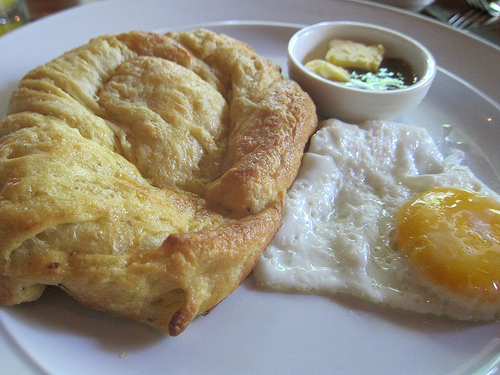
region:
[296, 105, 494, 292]
fried egg on white plate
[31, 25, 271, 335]
large brown danish on white plate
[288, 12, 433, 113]
white round sauce cup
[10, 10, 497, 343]
breakfast food on round white plate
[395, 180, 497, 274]
yellow round egg yolk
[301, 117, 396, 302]
white fried egg on plate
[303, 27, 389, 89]
slices of butter in sauce cup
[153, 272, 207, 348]
crusty brown burnt part on danish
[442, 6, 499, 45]
prongs on end of silver fork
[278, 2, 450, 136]
sauce cup sitting on plate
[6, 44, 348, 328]
the plate is white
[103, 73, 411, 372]
the plate is white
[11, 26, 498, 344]
the food on the plate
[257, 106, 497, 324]
the egg on the plate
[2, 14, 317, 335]
the pastry on the plate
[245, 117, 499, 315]
the egg is fried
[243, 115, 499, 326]
the omelette is on the plate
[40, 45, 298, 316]
the pastry is flaky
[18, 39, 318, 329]
the pastry is toasted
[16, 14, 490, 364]
the omelette is oily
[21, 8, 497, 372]
a white plate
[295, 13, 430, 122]
some dipping syrup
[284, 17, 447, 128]
a small white bowl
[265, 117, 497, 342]
a fried egg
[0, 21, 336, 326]
A breakfast pastry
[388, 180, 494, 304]
the egg yolk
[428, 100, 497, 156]
some reflections of the ceiling on the plate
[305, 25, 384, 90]
butter in the syrup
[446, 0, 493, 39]
a silver fork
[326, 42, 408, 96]
the reflection of light in the syrup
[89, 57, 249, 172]
tan lemon danish on plate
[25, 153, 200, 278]
tan lemon danish on plate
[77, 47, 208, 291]
tan lemon danish on plate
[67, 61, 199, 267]
tan lemon danish on white plate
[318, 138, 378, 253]
white eggs on plate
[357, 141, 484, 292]
yellow eggs on plate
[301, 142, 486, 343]
yellow eggs on white plate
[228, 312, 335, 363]
white plate holding breakfast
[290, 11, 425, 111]
white bowl on white plate holding food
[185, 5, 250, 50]
white plate holding breakfast